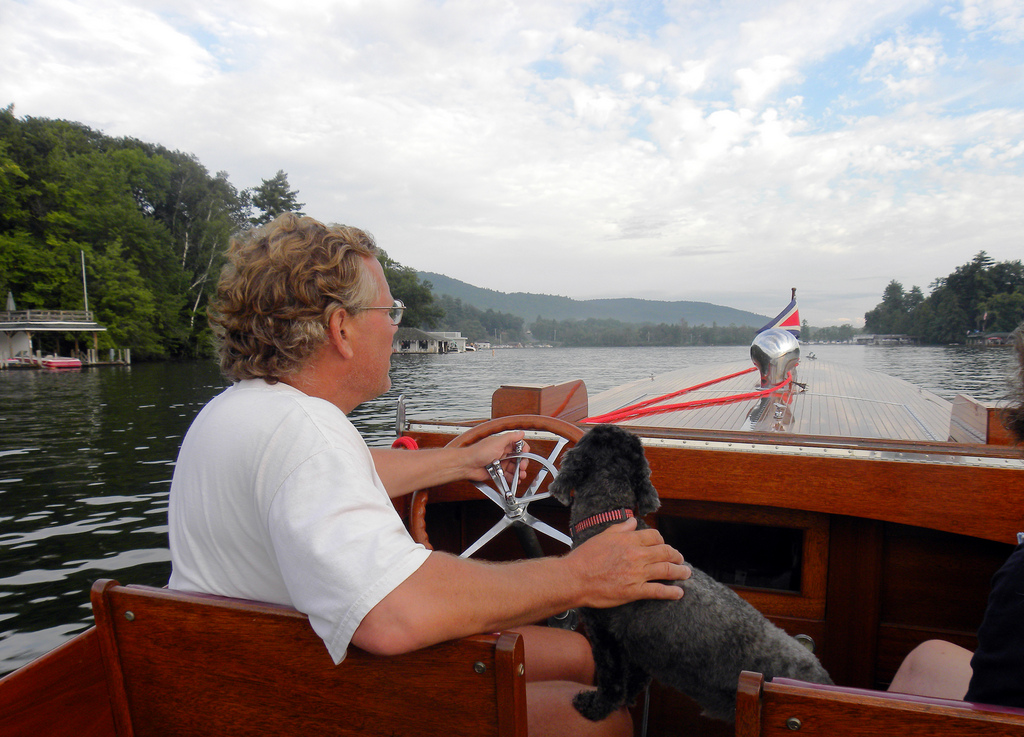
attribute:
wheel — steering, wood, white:
[409, 410, 616, 575]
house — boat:
[2, 289, 127, 370]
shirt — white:
[166, 377, 428, 663]